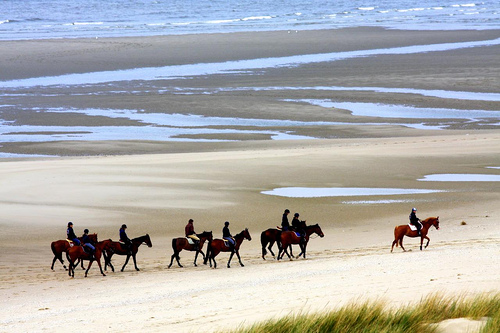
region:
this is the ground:
[143, 303, 197, 327]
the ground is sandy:
[177, 286, 224, 328]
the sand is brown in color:
[140, 284, 207, 325]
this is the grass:
[302, 315, 342, 331]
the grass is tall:
[306, 317, 348, 331]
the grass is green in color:
[336, 307, 380, 331]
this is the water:
[127, 9, 164, 22]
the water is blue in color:
[125, 8, 152, 20]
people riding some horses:
[35, 207, 440, 262]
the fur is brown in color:
[70, 247, 82, 256]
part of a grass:
[353, 290, 369, 318]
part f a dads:
[363, 245, 383, 271]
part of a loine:
[339, 236, 356, 274]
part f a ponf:
[331, 151, 383, 236]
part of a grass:
[350, 300, 364, 322]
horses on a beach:
[13, 61, 493, 318]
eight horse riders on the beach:
[40, 201, 465, 272]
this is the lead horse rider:
[375, 195, 468, 250]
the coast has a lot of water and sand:
[20, 29, 490, 155]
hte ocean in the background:
[9, 4, 484, 36]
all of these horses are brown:
[41, 208, 445, 293]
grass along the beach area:
[247, 297, 492, 332]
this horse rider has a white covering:
[389, 201, 441, 257]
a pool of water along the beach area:
[258, 180, 449, 201]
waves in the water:
[5, 4, 495, 18]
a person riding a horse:
[384, 190, 441, 254]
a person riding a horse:
[280, 212, 329, 257]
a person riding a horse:
[254, 201, 297, 258]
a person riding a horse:
[204, 215, 254, 265]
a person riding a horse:
[166, 206, 213, 279]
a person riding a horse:
[106, 216, 153, 269]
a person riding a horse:
[49, 213, 99, 263]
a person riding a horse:
[70, 227, 116, 274]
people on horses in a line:
[50, 198, 452, 281]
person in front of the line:
[388, 205, 443, 250]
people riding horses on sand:
[278, 207, 310, 239]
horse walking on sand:
[109, 236, 154, 269]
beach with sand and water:
[9, 8, 485, 302]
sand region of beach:
[15, 163, 492, 305]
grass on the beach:
[246, 296, 498, 331]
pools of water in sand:
[255, 178, 426, 204]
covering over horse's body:
[188, 235, 196, 247]